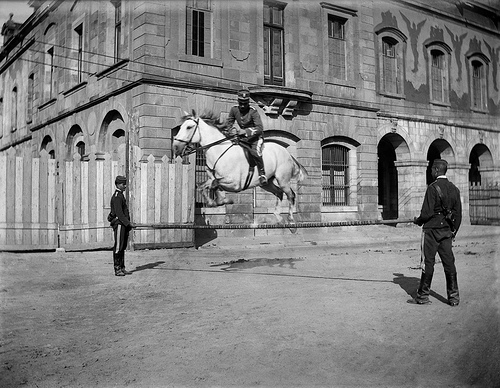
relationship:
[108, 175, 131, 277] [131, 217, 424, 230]
man holding left side of pole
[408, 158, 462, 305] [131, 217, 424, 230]
man holding right side pole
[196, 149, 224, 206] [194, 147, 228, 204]
bars on window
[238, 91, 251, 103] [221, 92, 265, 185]
hat on man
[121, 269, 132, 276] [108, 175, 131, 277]
foot of man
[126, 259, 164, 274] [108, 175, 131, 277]
shadow of man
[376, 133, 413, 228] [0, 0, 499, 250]
archway of building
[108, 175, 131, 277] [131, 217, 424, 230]
man holding pole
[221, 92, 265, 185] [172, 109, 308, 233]
man riding horse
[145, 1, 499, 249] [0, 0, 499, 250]
facade of a building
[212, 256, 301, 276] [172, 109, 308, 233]
shadow of a horse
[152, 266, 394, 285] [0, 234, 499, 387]
shadow on ground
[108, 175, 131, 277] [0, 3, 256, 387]
man on right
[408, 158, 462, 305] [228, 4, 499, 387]
man on left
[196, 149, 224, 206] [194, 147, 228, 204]
bars in window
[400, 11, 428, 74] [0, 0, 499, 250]
angel on side of building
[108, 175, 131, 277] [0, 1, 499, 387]
man in photo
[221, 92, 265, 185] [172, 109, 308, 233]
man riding a horse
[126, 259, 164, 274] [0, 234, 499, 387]
shadow on ground